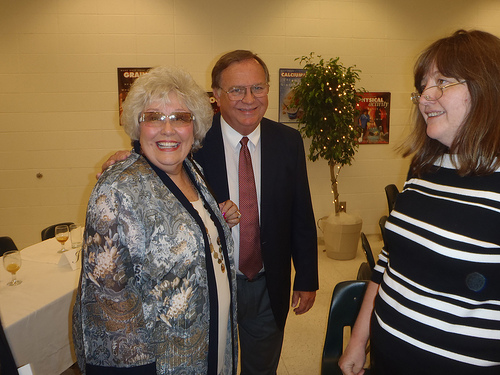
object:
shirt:
[361, 140, 498, 372]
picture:
[276, 67, 307, 124]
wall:
[0, 3, 493, 252]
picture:
[351, 90, 388, 143]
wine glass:
[56, 224, 69, 254]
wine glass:
[2, 248, 22, 287]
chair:
[321, 279, 375, 374]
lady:
[338, 30, 500, 375]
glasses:
[408, 80, 470, 104]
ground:
[232, 229, 387, 375]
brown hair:
[397, 29, 496, 178]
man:
[94, 49, 318, 374]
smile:
[234, 105, 259, 112]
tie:
[233, 133, 265, 282]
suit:
[193, 113, 318, 375]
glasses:
[2, 251, 24, 287]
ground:
[337, 107, 377, 141]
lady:
[72, 66, 244, 373]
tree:
[287, 55, 374, 213]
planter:
[317, 213, 361, 261]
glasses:
[138, 110, 193, 127]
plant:
[291, 53, 364, 216]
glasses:
[408, 81, 464, 105]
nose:
[417, 79, 437, 104]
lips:
[148, 136, 190, 156]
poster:
[352, 87, 392, 146]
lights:
[307, 63, 364, 211]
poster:
[276, 67, 312, 126]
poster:
[116, 65, 156, 130]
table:
[0, 224, 84, 374]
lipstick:
[154, 140, 179, 151]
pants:
[233, 268, 283, 373]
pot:
[314, 214, 362, 262]